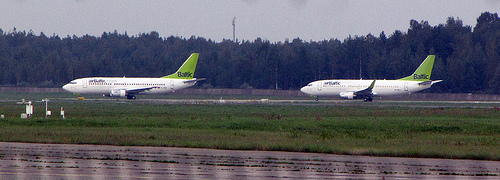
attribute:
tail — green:
[164, 52, 204, 82]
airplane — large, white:
[52, 52, 207, 104]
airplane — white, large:
[300, 51, 447, 108]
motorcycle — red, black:
[361, 88, 381, 107]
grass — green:
[128, 81, 451, 145]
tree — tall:
[445, 21, 480, 95]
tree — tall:
[408, 19, 427, 83]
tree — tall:
[475, 16, 497, 85]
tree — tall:
[282, 42, 303, 90]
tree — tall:
[349, 38, 366, 80]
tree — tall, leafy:
[341, 37, 363, 79]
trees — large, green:
[10, 15, 497, 90]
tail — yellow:
[408, 49, 440, 79]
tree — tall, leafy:
[285, 36, 301, 99]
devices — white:
[13, 97, 66, 121]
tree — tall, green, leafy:
[362, 35, 392, 81]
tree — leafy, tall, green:
[407, 18, 435, 80]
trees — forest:
[7, 16, 499, 51]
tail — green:
[395, 53, 437, 82]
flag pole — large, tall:
[217, 10, 252, 71]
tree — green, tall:
[4, 38, 43, 83]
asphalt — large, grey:
[283, 102, 486, 107]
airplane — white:
[297, 55, 441, 98]